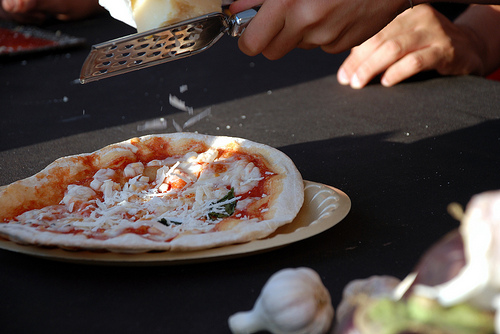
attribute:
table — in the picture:
[0, 20, 499, 332]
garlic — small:
[67, 183, 94, 201]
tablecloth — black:
[0, 15, 499, 332]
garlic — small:
[450, 190, 499, 306]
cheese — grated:
[92, 173, 272, 240]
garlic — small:
[83, 22, 230, 64]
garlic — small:
[254, 272, 340, 329]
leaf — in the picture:
[210, 183, 267, 220]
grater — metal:
[77, 1, 269, 89]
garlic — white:
[218, 259, 374, 328]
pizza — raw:
[76, 130, 289, 249]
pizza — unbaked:
[17, 122, 323, 276]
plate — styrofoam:
[0, 174, 355, 262]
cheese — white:
[28, 156, 253, 232]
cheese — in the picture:
[80, 104, 254, 204]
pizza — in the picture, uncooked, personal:
[0, 128, 306, 253]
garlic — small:
[225, 266, 331, 332]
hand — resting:
[335, 2, 480, 91]